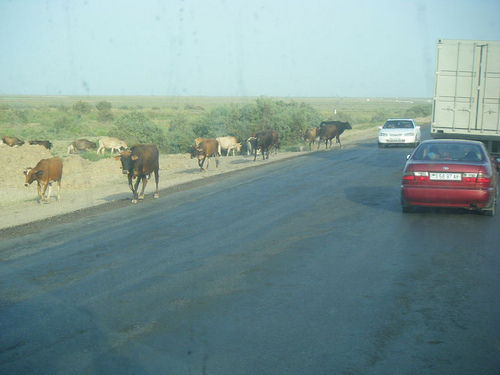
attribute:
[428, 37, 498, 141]
trailer — on road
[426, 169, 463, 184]
number — on the car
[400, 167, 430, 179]
light — red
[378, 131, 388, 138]
headlight — red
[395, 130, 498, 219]
car — on road, red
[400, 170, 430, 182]
tail light — red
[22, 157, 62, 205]
cow — light brown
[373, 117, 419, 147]
car highway — on road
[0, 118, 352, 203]
cows — on road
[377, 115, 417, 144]
car — white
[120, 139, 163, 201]
cow — dark brown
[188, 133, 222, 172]
cow — dark brown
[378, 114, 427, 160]
car — white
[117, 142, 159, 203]
cow — brown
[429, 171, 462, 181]
license plate — white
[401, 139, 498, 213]
car — red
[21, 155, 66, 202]
cow — dark brown, on road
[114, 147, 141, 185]
head — of cow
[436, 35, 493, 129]
doors — on the car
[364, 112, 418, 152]
car — white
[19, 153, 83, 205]
cow — white, brown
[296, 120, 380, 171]
cow — walking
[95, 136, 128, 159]
cow — white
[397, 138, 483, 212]
car — red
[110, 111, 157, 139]
bush — green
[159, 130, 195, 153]
bush — green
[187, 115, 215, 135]
bush — green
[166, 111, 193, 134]
bush — green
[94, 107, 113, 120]
bush — green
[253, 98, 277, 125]
tree — green, leafy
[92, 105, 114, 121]
tree — green, leafy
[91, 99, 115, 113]
tree — green, leafy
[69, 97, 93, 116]
tree — green, leafy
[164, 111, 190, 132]
tree — green, leafy